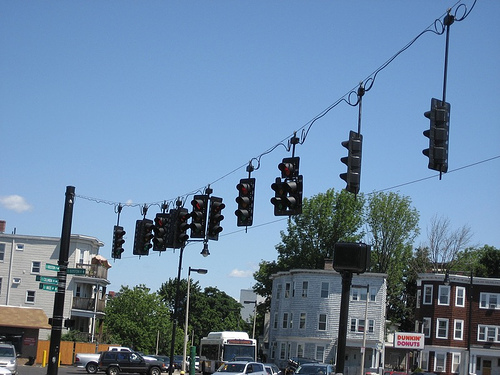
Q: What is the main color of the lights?
A: Black.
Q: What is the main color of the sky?
A: Blue.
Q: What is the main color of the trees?
A: Green.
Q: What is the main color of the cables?
A: Black.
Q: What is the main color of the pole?
A: Black.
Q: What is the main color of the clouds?
A: White.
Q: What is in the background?
A: Tree tops.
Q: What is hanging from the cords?
A: Traffic lights.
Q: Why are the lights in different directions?
A: For drivers.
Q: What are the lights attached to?
A: Pole.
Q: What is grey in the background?
A: Building.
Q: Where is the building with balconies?
A: Left.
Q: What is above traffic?
A: Lights.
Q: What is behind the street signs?
A: Tan building.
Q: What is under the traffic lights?
A: Grey house.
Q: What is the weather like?
A: Clear.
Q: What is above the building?
A: Trees.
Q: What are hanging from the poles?
A: Traffic lights.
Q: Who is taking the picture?
A: A photographer.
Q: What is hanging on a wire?
A: Traffic lights.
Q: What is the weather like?
A: Sunny and clear.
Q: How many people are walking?
A: No one walking.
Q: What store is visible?
A: Dunkin donuts.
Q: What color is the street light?
A: It is red.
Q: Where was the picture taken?
A: On a street corner.